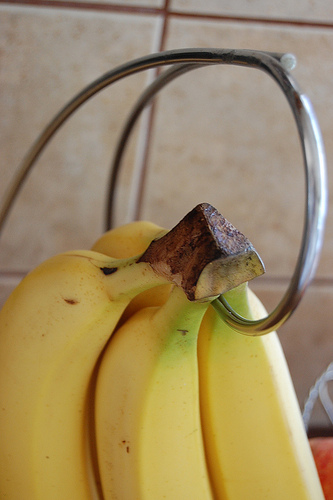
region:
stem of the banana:
[187, 210, 221, 279]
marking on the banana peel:
[116, 439, 133, 457]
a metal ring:
[254, 311, 280, 329]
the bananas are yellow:
[16, 340, 282, 495]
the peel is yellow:
[106, 376, 193, 498]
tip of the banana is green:
[171, 306, 204, 346]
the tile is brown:
[204, 114, 282, 182]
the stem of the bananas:
[180, 223, 235, 266]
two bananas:
[1, 283, 203, 499]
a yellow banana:
[208, 364, 299, 498]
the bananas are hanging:
[1, 17, 332, 495]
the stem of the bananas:
[144, 192, 270, 316]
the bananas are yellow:
[12, 199, 318, 499]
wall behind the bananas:
[9, 0, 322, 352]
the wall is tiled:
[4, 4, 332, 291]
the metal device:
[14, 37, 323, 330]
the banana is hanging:
[91, 282, 225, 498]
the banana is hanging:
[212, 285, 329, 499]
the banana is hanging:
[4, 250, 124, 499]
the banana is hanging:
[81, 203, 177, 309]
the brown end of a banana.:
[141, 201, 265, 301]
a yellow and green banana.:
[94, 283, 221, 498]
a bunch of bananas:
[0, 200, 326, 497]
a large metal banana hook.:
[0, 39, 327, 334]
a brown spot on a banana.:
[58, 286, 87, 313]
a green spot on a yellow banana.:
[157, 284, 227, 365]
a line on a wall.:
[130, 0, 187, 225]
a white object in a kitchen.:
[298, 344, 331, 440]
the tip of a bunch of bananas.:
[139, 196, 272, 305]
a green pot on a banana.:
[147, 288, 217, 368]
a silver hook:
[1, 42, 329, 336]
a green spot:
[111, 251, 252, 355]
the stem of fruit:
[138, 198, 267, 299]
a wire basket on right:
[301, 364, 331, 435]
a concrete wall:
[3, 0, 331, 424]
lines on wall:
[0, 2, 330, 287]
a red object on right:
[309, 437, 330, 498]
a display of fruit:
[1, 46, 328, 499]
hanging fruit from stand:
[0, 201, 325, 497]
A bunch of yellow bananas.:
[0, 200, 327, 499]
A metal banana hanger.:
[1, 47, 331, 336]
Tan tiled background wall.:
[0, 1, 332, 439]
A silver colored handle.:
[300, 363, 332, 437]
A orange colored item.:
[308, 435, 332, 499]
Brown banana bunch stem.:
[138, 202, 265, 303]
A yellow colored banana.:
[198, 282, 327, 498]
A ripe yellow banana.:
[93, 292, 218, 498]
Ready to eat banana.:
[0, 246, 168, 499]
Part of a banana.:
[90, 217, 177, 263]